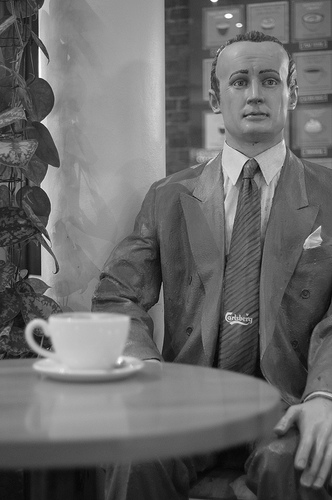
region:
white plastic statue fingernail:
[296, 455, 304, 464]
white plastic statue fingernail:
[299, 471, 310, 481]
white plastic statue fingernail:
[307, 476, 320, 483]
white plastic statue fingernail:
[271, 422, 282, 428]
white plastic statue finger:
[272, 399, 293, 429]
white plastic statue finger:
[291, 426, 308, 464]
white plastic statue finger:
[297, 437, 315, 482]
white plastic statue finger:
[312, 440, 324, 485]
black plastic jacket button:
[183, 273, 195, 283]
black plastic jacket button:
[299, 286, 309, 300]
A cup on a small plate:
[26, 311, 128, 365]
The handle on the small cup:
[25, 319, 55, 357]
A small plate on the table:
[36, 356, 141, 377]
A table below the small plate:
[0, 357, 280, 470]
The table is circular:
[0, 358, 281, 470]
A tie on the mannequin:
[218, 159, 261, 368]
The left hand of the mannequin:
[277, 400, 331, 486]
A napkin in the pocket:
[304, 226, 322, 247]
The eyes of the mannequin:
[228, 78, 278, 86]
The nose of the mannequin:
[246, 83, 265, 102]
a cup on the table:
[17, 297, 138, 391]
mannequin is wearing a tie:
[173, 129, 277, 425]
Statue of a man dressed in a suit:
[186, 28, 329, 290]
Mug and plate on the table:
[18, 303, 165, 385]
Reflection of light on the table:
[42, 384, 210, 429]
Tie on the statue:
[231, 169, 304, 344]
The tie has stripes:
[227, 251, 257, 295]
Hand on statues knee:
[274, 376, 331, 494]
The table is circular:
[169, 341, 278, 476]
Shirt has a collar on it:
[211, 137, 297, 183]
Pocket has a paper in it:
[290, 213, 329, 249]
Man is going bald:
[213, 25, 322, 80]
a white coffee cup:
[27, 307, 144, 380]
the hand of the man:
[277, 395, 331, 474]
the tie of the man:
[222, 164, 261, 376]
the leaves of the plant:
[2, 3, 69, 312]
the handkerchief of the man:
[299, 226, 327, 260]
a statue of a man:
[187, 39, 322, 178]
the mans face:
[200, 36, 307, 178]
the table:
[4, 344, 302, 472]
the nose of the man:
[244, 81, 269, 107]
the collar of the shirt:
[218, 142, 286, 189]